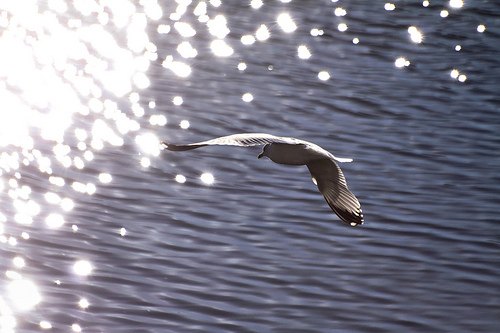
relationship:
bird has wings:
[158, 121, 372, 233] [166, 131, 375, 230]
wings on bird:
[166, 131, 375, 230] [158, 121, 372, 233]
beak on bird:
[256, 148, 267, 158] [158, 121, 372, 233]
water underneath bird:
[4, 7, 499, 330] [158, 121, 372, 233]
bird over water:
[158, 121, 372, 233] [4, 7, 499, 330]